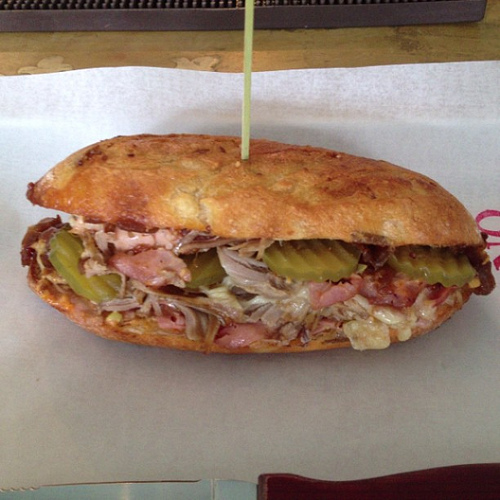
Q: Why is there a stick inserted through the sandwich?
A: It's used to hold the contents of the sandwich.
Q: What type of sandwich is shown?
A: Cold sub.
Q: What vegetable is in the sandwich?
A: Pickles.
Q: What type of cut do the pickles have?
A: Crinkle cut.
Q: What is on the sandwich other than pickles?
A: Meat.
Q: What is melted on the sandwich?
A: Cheese.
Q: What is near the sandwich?
A: A knife.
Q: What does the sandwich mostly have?
A: Meat.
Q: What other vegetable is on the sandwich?
A: Onion.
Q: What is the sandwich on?
A: Deli paper.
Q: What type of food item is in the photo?
A: A sandwich.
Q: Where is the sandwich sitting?
A: On paper.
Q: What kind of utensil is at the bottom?
A: A knife.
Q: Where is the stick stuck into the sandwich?
A: On the top.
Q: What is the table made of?
A: Wood.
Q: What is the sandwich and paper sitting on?
A: A table.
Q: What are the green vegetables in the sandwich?
A: Pickles.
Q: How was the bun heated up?
A: It was toasted.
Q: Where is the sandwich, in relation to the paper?
A: On top.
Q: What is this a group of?
A: Cold cut meats and cheese.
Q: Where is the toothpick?
A: Top layer of the toasted bread.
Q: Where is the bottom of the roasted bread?
A: On white surface.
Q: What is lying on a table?
A: Sub.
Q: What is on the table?
A: Sandwich with pork,ham, cheese and pickles.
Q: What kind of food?
A: Lightly toasted sandwich bun.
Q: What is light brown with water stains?
A: Table.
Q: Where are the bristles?
A: On dark brown mat.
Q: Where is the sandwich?
A: Sitting on white paper.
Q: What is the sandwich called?
A: A hoagie, hero, sub, or other.